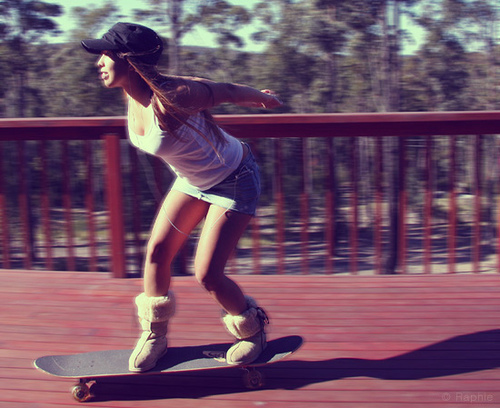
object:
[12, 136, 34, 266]
post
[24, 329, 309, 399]
skateboard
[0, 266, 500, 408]
deck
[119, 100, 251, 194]
tank top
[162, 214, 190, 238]
wire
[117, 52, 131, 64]
earphones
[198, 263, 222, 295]
knee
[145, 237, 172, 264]
knee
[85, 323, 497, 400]
shadow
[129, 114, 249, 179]
white shirt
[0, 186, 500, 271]
ground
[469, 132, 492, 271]
post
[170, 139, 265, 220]
blue jean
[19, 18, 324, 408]
skateboarding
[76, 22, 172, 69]
black hat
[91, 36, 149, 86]
girl's head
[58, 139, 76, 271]
wooden post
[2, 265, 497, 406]
porch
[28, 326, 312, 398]
longboard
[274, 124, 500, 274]
fence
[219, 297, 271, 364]
brown boot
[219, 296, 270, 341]
fur trim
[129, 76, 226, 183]
top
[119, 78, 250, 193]
shirt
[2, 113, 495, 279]
railing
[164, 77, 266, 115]
arm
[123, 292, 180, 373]
boot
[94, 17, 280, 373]
girl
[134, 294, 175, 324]
trim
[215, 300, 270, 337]
trim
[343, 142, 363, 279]
post